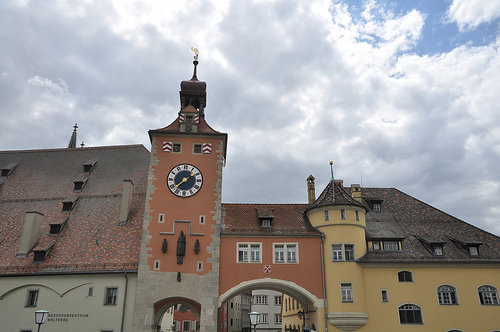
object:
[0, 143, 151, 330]
building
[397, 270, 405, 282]
window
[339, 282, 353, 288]
window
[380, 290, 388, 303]
window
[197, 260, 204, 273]
window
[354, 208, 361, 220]
window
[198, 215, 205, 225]
window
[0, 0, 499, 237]
cloud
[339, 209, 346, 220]
window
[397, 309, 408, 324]
window